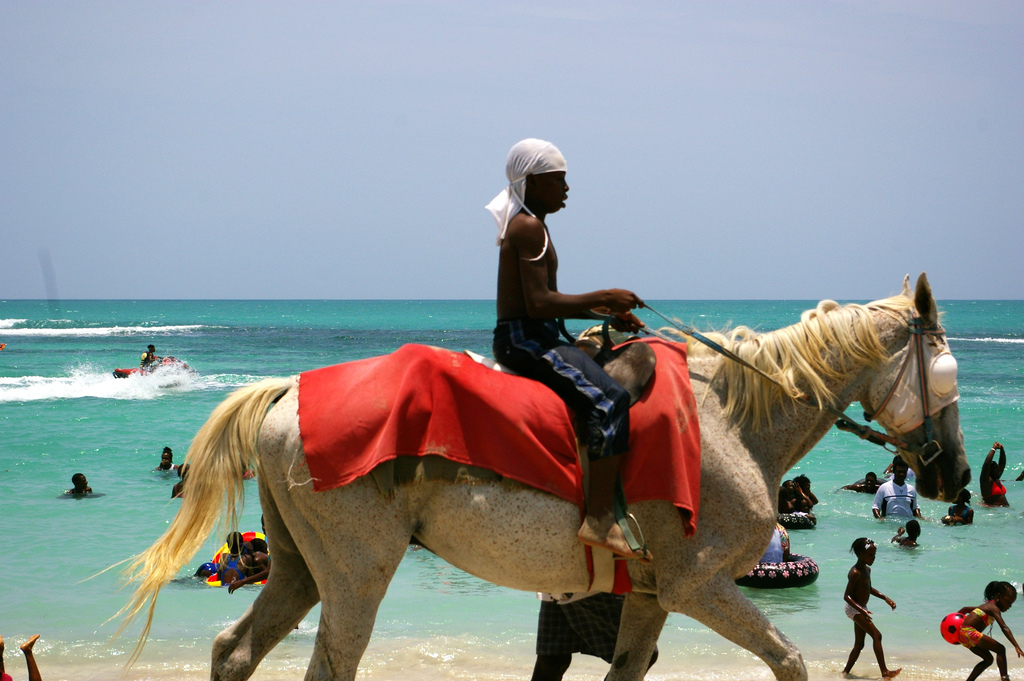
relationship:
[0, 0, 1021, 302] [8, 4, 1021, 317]
sky in sky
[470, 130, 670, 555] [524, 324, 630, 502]
man wearing pants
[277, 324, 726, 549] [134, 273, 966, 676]
blanket on horse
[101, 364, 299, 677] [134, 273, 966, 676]
tail on horse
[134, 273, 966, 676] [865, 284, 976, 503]
horse has face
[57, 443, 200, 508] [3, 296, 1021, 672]
people playing in water